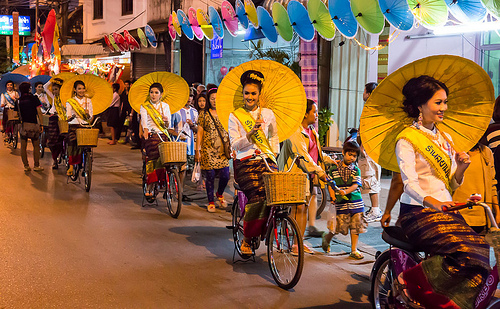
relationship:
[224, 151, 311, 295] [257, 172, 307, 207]
bicycle has a basket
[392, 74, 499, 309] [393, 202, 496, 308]
girl in dress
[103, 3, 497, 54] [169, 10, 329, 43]
umbrellas in a group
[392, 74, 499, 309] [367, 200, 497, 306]
girl on a bike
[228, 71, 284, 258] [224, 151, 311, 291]
girl on bicycle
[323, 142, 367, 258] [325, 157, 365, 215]
boy with striped shirt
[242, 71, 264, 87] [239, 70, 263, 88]
flowers in hair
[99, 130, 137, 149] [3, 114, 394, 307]
edge of road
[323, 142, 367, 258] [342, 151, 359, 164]
boy has face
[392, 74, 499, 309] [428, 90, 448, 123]
girl has face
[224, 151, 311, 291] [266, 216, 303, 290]
bicycle has wheel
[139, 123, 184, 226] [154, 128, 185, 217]
bike has front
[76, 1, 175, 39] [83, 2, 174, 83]
part of building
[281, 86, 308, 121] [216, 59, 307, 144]
part of umbrella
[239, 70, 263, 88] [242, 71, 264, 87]
hair has flowers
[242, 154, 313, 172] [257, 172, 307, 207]
handles above basket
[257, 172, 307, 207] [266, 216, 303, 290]
basket above wheel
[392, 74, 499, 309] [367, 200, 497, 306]
girl riding bike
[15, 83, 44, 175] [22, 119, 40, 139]
man has bag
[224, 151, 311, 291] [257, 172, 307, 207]
bicycle has basket